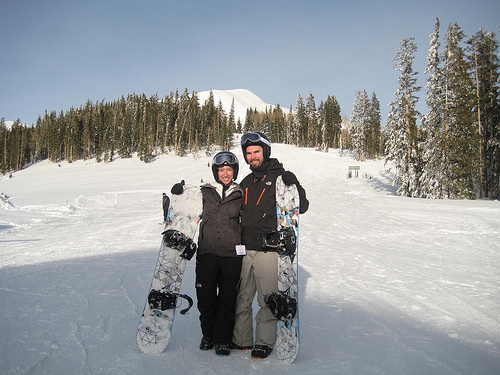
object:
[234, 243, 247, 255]
tag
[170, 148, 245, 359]
woman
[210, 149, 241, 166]
googles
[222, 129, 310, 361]
man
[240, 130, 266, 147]
goggles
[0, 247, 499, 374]
shadow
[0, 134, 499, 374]
snow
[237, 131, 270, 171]
head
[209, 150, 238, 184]
head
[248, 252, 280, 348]
leg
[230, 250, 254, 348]
leg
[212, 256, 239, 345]
leg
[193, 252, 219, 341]
leg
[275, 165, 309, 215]
arm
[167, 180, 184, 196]
glove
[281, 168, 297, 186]
glove